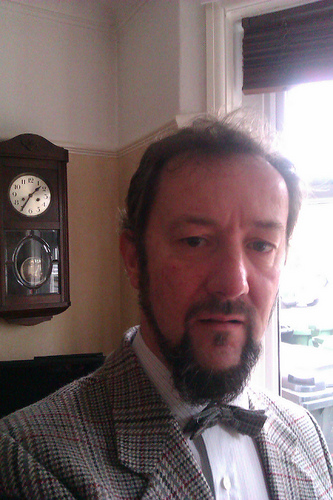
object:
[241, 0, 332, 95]
curtains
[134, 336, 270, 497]
shirt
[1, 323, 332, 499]
suit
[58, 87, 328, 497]
man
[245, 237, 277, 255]
eye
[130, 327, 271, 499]
collared shirt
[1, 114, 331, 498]
guy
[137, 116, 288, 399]
guy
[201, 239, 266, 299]
nose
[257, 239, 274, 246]
eye lash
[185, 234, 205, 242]
eye lash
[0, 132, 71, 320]
clock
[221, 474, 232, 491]
button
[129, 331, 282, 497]
shirt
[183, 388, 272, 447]
tie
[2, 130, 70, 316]
wood clock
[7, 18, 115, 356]
wall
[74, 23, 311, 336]
scene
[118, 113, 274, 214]
hair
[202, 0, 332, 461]
window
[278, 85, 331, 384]
sunlight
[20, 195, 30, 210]
hands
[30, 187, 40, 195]
hands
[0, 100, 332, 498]
man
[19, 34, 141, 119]
wall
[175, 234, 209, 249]
eye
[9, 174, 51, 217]
face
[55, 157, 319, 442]
guy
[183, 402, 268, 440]
bow tie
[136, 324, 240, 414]
neck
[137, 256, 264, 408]
beard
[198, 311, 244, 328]
mouth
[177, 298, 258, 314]
mustache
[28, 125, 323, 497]
person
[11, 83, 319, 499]
man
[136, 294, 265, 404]
facial hair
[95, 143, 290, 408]
guy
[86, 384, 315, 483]
jacket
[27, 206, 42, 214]
numbers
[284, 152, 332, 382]
day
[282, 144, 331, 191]
sun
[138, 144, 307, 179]
hair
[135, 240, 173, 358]
burns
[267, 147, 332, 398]
window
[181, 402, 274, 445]
tie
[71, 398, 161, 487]
jacket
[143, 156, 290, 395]
face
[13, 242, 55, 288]
pendulum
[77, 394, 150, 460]
jacket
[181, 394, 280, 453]
tie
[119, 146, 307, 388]
man